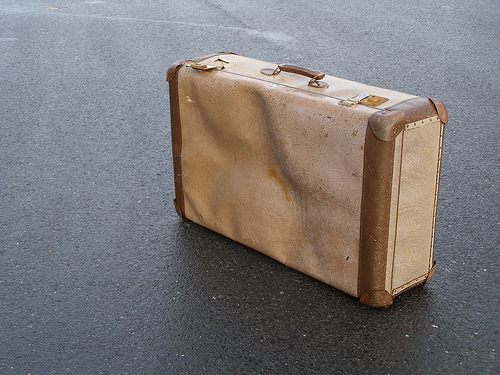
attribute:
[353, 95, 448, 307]
trim — brown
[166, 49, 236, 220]
trim — brown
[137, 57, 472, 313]
suitcase — brown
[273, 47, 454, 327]
luggage — light, brown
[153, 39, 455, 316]
suitcase — brown, mark, tan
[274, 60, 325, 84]
handle — brown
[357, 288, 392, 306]
corner protector — brown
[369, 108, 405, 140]
corner protector — brown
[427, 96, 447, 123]
corner protector — brown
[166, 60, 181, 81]
corner protector — brown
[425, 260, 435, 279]
corner protector — brown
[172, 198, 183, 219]
corner protector — brown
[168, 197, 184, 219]
corner — brown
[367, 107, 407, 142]
protector — brown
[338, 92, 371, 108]
latch — gold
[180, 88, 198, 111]
mark — white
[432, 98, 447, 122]
corner protector — brown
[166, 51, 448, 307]
suitcase — brown